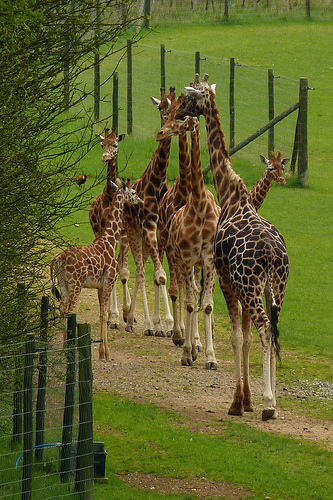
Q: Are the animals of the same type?
A: Yes, all the animals are giraffes.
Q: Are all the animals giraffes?
A: Yes, all the animals are giraffes.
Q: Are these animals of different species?
A: No, all the animals are giraffes.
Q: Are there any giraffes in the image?
A: Yes, there is a giraffe.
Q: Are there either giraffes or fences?
A: Yes, there is a giraffe.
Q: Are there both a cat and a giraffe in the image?
A: No, there is a giraffe but no cats.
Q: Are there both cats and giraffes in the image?
A: No, there is a giraffe but no cats.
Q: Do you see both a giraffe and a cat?
A: No, there is a giraffe but no cats.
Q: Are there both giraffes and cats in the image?
A: No, there is a giraffe but no cats.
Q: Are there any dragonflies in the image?
A: No, there are no dragonflies.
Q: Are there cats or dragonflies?
A: No, there are no dragonflies or cats.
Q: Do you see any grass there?
A: Yes, there is grass.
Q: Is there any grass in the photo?
A: Yes, there is grass.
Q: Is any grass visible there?
A: Yes, there is grass.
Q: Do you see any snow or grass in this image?
A: Yes, there is grass.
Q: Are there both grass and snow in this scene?
A: No, there is grass but no snow.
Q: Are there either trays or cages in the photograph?
A: No, there are no cages or trays.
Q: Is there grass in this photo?
A: Yes, there is grass.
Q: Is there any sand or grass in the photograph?
A: Yes, there is grass.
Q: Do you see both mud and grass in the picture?
A: No, there is grass but no mud.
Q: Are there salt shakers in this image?
A: No, there are no salt shakers.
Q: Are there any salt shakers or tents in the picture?
A: No, there are no salt shakers or tents.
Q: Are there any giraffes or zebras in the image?
A: Yes, there is a giraffe.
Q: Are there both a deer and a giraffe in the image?
A: No, there is a giraffe but no deer.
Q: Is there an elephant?
A: No, there are no elephants.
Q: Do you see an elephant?
A: No, there are no elephants.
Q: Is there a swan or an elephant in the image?
A: No, there are no elephants or swans.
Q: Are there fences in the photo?
A: Yes, there is a fence.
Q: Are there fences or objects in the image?
A: Yes, there is a fence.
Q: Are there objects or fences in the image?
A: Yes, there is a fence.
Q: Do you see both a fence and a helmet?
A: No, there is a fence but no helmets.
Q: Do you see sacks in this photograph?
A: No, there are no sacks.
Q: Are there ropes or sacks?
A: No, there are no sacks or ropes.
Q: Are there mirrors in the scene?
A: No, there are no mirrors.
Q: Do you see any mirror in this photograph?
A: No, there are no mirrors.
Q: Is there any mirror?
A: No, there are no mirrors.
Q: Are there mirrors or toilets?
A: No, there are no mirrors or toilets.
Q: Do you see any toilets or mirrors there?
A: No, there are no mirrors or toilets.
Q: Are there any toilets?
A: No, there are no toilets.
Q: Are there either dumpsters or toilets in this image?
A: No, there are no toilets or dumpsters.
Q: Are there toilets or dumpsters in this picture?
A: No, there are no toilets or dumpsters.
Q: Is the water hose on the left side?
A: Yes, the water hose is on the left of the image.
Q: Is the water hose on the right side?
A: No, the water hose is on the left of the image.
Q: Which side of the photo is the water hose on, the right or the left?
A: The water hose is on the left of the image.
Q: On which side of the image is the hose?
A: The hose is on the left of the image.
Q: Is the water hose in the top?
A: No, the water hose is in the bottom of the image.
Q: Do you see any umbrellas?
A: No, there are no umbrellas.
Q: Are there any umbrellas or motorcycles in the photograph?
A: No, there are no umbrellas or motorcycles.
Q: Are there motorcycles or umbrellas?
A: No, there are no umbrellas or motorcycles.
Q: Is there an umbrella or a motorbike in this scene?
A: No, there are no umbrellas or motorcycles.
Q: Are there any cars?
A: No, there are no cars.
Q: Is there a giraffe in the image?
A: Yes, there is a giraffe.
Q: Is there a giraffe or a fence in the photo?
A: Yes, there is a giraffe.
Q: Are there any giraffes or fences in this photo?
A: Yes, there is a giraffe.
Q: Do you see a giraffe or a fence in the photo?
A: Yes, there is a giraffe.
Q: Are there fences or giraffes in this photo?
A: Yes, there is a giraffe.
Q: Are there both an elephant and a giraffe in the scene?
A: No, there is a giraffe but no elephants.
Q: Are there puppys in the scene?
A: No, there are no puppys.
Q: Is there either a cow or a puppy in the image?
A: No, there are no puppys or cows.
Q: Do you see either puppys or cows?
A: No, there are no puppys or cows.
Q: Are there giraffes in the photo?
A: Yes, there is a giraffe.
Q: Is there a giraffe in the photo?
A: Yes, there is a giraffe.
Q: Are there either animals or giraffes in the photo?
A: Yes, there is a giraffe.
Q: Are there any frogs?
A: No, there are no frogs.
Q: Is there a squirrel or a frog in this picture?
A: No, there are no frogs or squirrels.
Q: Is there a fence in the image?
A: Yes, there is a fence.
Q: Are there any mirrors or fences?
A: Yes, there is a fence.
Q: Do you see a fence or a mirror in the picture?
A: Yes, there is a fence.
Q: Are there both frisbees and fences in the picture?
A: No, there is a fence but no frisbees.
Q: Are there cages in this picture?
A: No, there are no cages.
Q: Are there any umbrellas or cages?
A: No, there are no cages or umbrellas.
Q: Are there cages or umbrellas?
A: No, there are no cages or umbrellas.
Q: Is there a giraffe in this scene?
A: Yes, there is a giraffe.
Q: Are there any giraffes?
A: Yes, there is a giraffe.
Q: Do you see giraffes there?
A: Yes, there is a giraffe.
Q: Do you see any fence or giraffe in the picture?
A: Yes, there is a giraffe.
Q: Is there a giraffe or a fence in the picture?
A: Yes, there is a giraffe.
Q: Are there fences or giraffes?
A: Yes, there is a giraffe.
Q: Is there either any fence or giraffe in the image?
A: Yes, there is a giraffe.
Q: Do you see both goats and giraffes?
A: No, there is a giraffe but no goats.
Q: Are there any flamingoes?
A: No, there are no flamingoes.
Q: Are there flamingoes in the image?
A: No, there are no flamingoes.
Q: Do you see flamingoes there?
A: No, there are no flamingoes.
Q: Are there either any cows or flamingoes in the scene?
A: No, there are no flamingoes or cows.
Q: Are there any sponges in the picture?
A: No, there are no sponges.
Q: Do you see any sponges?
A: No, there are no sponges.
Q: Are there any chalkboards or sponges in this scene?
A: No, there are no sponges or chalkboards.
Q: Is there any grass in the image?
A: Yes, there is grass.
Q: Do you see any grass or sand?
A: Yes, there is grass.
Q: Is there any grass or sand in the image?
A: Yes, there is grass.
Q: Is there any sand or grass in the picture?
A: Yes, there is grass.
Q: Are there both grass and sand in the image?
A: No, there is grass but no sand.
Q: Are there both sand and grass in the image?
A: No, there is grass but no sand.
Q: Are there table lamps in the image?
A: No, there are no table lamps.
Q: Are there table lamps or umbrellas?
A: No, there are no table lamps or umbrellas.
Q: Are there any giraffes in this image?
A: Yes, there is a giraffe.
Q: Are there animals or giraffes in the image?
A: Yes, there is a giraffe.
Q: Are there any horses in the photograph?
A: No, there are no horses.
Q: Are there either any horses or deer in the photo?
A: No, there are no horses or deer.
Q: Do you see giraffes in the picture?
A: Yes, there is a giraffe.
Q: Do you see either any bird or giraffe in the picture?
A: Yes, there is a giraffe.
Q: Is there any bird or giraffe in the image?
A: Yes, there is a giraffe.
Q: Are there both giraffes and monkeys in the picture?
A: No, there is a giraffe but no monkeys.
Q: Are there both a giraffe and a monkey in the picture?
A: No, there is a giraffe but no monkeys.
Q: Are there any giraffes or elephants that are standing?
A: Yes, the giraffe is standing.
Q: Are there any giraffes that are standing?
A: Yes, there is a giraffe that is standing.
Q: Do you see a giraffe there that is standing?
A: Yes, there is a giraffe that is standing.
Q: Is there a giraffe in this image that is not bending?
A: Yes, there is a giraffe that is standing.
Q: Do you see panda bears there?
A: No, there are no panda bears.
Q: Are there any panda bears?
A: No, there are no panda bears.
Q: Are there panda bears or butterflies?
A: No, there are no panda bears or butterflies.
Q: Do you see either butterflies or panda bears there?
A: No, there are no panda bears or butterflies.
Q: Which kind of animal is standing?
A: The animal is a giraffe.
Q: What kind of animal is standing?
A: The animal is a giraffe.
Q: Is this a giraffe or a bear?
A: This is a giraffe.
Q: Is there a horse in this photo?
A: No, there are no horses.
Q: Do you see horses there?
A: No, there are no horses.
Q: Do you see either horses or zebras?
A: No, there are no horses or zebras.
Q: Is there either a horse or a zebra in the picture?
A: No, there are no horses or zebras.